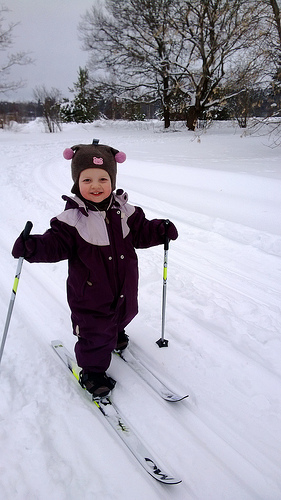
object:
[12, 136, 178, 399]
girl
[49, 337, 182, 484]
skis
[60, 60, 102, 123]
trees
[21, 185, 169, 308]
jacket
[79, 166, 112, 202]
face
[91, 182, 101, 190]
nose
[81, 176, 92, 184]
eyes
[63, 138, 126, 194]
cap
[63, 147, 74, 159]
ball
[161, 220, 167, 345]
pole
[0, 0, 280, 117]
sky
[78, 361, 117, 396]
boot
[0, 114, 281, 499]
snow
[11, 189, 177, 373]
suit